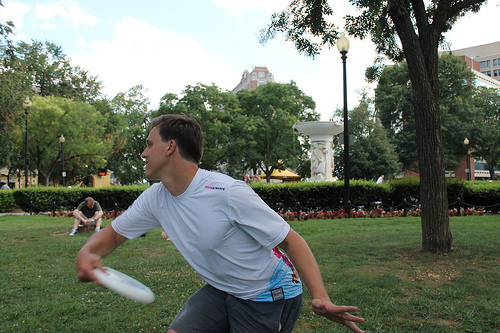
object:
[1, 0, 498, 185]
leaf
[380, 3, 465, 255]
tree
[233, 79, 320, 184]
tree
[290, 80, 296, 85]
leaf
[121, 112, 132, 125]
green leaf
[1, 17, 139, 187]
tree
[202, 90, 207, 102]
leaf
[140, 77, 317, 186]
tree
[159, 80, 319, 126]
green leaf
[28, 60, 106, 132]
leaf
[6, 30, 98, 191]
tree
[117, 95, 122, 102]
leaf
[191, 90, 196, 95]
leaf